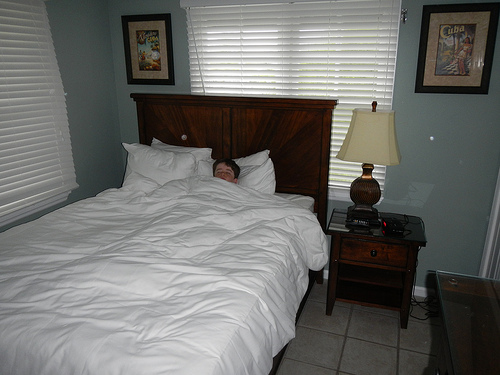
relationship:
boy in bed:
[210, 159, 243, 184] [4, 92, 340, 374]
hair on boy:
[212, 158, 244, 177] [210, 159, 243, 184]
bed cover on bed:
[0, 172, 330, 374] [4, 92, 340, 374]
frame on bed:
[268, 268, 322, 375] [4, 92, 340, 374]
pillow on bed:
[198, 147, 277, 197] [4, 92, 340, 374]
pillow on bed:
[119, 141, 195, 188] [4, 92, 340, 374]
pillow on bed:
[151, 135, 212, 177] [4, 92, 340, 374]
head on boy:
[211, 156, 241, 185] [210, 159, 243, 184]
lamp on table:
[337, 99, 405, 204] [324, 206, 428, 329]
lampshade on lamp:
[335, 109, 407, 168] [337, 99, 405, 204]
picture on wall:
[119, 13, 179, 87] [108, 0, 499, 285]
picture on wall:
[416, 0, 498, 95] [108, 0, 499, 285]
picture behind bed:
[119, 13, 179, 87] [4, 92, 340, 374]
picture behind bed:
[416, 0, 498, 95] [4, 92, 340, 374]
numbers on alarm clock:
[380, 219, 391, 228] [380, 217, 406, 236]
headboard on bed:
[128, 91, 337, 198] [4, 92, 340, 374]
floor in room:
[276, 281, 431, 375] [0, 0, 498, 374]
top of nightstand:
[327, 206, 428, 247] [327, 206, 429, 328]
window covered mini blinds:
[186, 6, 403, 191] [178, 2, 403, 197]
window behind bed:
[186, 6, 403, 191] [4, 92, 340, 374]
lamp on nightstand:
[337, 99, 405, 204] [327, 206, 429, 328]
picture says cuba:
[416, 0, 498, 95] [438, 23, 469, 43]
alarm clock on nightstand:
[380, 217, 406, 236] [327, 206, 429, 328]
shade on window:
[181, 2, 404, 204] [186, 6, 403, 191]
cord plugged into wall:
[402, 215, 432, 322] [108, 0, 499, 285]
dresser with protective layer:
[325, 208, 428, 327] [330, 206, 428, 242]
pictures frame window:
[122, 2, 499, 96] [186, 6, 403, 191]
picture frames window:
[119, 13, 179, 87] [186, 6, 403, 191]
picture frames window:
[416, 0, 498, 95] [186, 6, 403, 191]